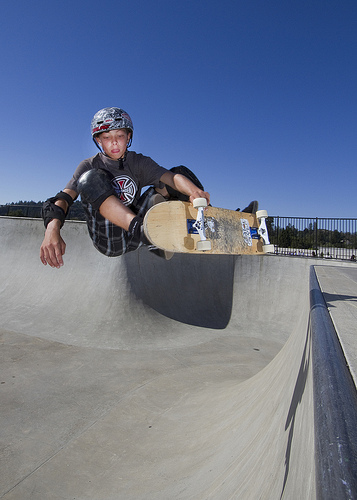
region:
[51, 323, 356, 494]
skate park ramp is concrete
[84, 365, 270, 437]
skate park ramp is concrete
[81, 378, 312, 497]
skate park ramp is concrete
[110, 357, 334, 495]
skate park ramp is concrete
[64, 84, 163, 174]
the boy is wearing a helmet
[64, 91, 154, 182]
the helmet is blue with red letters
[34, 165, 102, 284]
the boy has elbow pads on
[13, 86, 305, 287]
the boy is riding a skateboard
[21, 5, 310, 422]
the boy is at the skate park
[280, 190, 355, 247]
a railing is around the area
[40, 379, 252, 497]
the skate park is made of concrete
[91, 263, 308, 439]
the skate park has lots of hills, curves and other challenges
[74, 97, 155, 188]
the boy is very focused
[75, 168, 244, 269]
the boy is wearing knee pads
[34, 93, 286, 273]
skateboarding boy in the air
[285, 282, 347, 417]
shadow on skate ramp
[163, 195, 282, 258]
bottom of sideways skateboard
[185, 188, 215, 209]
hand holding edge of skateboard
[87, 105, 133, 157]
helmet on boy's head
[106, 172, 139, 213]
emblem on boy's shirt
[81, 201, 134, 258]
plaid shorts on skateboarder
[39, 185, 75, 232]
black pad on elbow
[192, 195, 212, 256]
white wheels on skateboard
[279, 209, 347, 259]
fence around skate park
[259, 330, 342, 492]
shadow is visible on ramp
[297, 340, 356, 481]
ramp bar is black and steel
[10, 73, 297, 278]
boy on a skateboard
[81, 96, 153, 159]
boy wearing a helmet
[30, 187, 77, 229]
boy wearing elbow guards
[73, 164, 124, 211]
a black knee pad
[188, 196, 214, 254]
wheels on the skateboard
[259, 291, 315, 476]
shadow on the side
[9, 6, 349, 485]
a clear bright day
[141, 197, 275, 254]
wood skateboard with white wheels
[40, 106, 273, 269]
boy riding wooden skateboard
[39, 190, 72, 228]
elbow pad on boy's arm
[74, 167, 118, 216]
knee pad on boy's leg